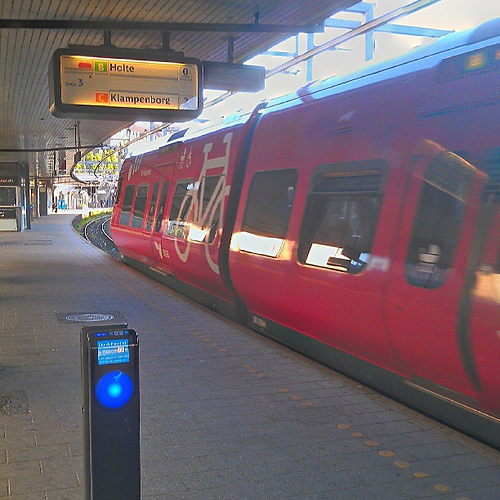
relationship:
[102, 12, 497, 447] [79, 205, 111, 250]
train on a track